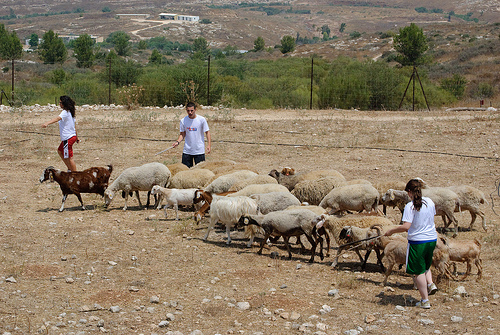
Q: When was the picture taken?
A: Daytime.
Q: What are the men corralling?
A: Sheep.